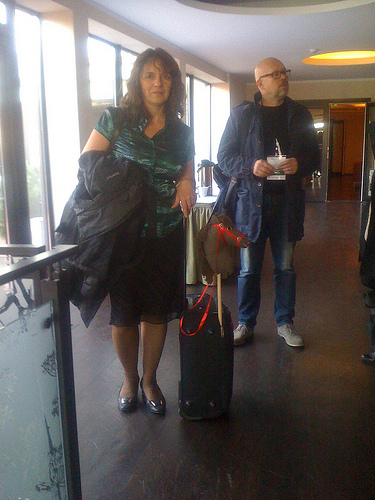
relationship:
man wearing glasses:
[217, 57, 321, 346] [256, 67, 294, 79]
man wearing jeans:
[215, 58, 312, 349] [238, 192, 299, 331]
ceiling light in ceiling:
[301, 50, 375, 66] [87, 0, 373, 81]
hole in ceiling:
[178, 0, 372, 16] [87, 0, 373, 81]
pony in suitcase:
[172, 211, 241, 352] [178, 287, 235, 422]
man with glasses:
[217, 57, 321, 346] [252, 66, 294, 81]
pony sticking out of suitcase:
[179, 212, 251, 337] [178, 287, 235, 422]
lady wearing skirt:
[54, 47, 196, 416] [94, 224, 187, 317]